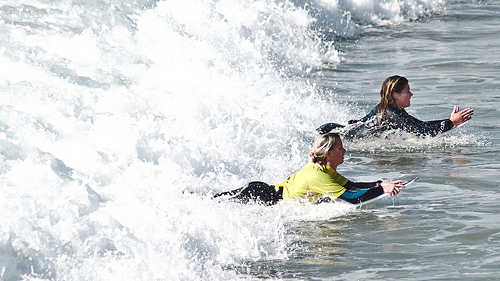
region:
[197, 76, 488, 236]
two women lying on surfboard in water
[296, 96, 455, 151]
black wet suit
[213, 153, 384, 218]
yellow t-shirt over black and blue swimsuit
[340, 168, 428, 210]
tip of surfboard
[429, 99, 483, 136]
hands on top of tip of surfboard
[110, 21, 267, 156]
white water splash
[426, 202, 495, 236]
white froth on top of water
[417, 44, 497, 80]
black ripples on surface of water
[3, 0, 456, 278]
large water waves in ocean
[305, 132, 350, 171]
head of blonde hair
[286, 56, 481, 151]
The girl is in the water.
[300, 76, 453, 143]
She is wearing a black wet suit.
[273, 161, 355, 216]
The shirt is yellow.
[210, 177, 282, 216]
The pants are black.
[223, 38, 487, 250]
They are on the board.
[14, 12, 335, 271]
The wave is small.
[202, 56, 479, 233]
They are laying on the boards.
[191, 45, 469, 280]
They are in the ocean.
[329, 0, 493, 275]
The water is blue.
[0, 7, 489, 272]
Two women in the ocean.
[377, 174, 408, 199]
a woman's hands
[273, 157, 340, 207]
a woman's yellow shirt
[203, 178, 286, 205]
a woman's black bodysuit pants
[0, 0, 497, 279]
the ocean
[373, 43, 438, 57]
a ripple from a wave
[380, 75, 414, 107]
a white woman's head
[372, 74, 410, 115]
wet hair on the surfer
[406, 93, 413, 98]
the nose on the surfer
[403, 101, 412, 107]
the surfer's chin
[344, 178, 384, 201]
the woman surfer's forearm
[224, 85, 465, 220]
two people swimming in the ocean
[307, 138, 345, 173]
the head of a blonde woman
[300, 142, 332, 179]
the hair of a blonde woman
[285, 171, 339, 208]
the shirt of a blonde woman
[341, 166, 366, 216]
the arm of a blonde woman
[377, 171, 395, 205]
the hand of a blonde woman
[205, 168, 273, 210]
the pants of a blonde woman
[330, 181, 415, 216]
the surfboard of a blonde woman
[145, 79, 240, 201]
waves crashing on two women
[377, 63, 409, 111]
the head of a brunette woman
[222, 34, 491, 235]
girls on the water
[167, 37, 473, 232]
girls riding the surfboards